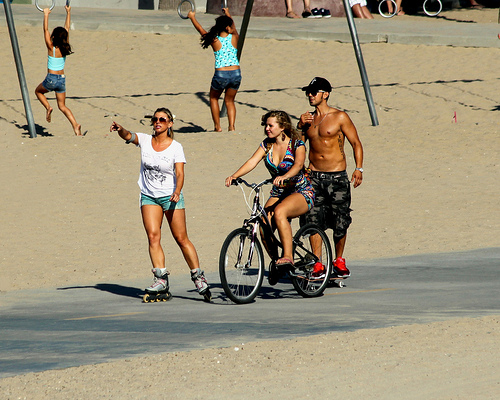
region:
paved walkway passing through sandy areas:
[2, 7, 497, 399]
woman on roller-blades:
[103, 105, 215, 302]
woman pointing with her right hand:
[106, 102, 185, 169]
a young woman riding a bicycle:
[216, 104, 333, 300]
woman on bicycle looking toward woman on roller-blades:
[106, 104, 334, 300]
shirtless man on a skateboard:
[296, 75, 368, 290]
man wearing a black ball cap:
[299, 74, 333, 111]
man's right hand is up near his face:
[290, 73, 371, 187]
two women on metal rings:
[3, 0, 381, 138]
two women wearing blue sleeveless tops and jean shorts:
[33, 1, 249, 131]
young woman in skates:
[109, 107, 216, 304]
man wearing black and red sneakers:
[294, 76, 364, 294]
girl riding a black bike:
[218, 109, 331, 303]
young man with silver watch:
[295, 74, 366, 289]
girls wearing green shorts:
[109, 105, 218, 304]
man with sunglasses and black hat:
[295, 74, 366, 289]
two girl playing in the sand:
[35, 7, 245, 136]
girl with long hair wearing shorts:
[187, 7, 243, 133]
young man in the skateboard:
[293, 76, 365, 288]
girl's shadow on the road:
[56, 279, 206, 319]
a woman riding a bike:
[207, 105, 309, 313]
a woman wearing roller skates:
[129, 104, 194, 325]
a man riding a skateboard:
[307, 57, 344, 305]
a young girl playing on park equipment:
[28, 1, 81, 134]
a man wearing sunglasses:
[289, 70, 333, 125]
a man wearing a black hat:
[302, 78, 334, 113]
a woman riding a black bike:
[223, 97, 300, 282]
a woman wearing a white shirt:
[115, 90, 200, 240]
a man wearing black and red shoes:
[316, 92, 346, 302]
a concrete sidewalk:
[38, 200, 483, 390]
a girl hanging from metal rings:
[21, 1, 98, 143]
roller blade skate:
[133, 267, 185, 307]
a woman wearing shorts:
[103, 96, 221, 332]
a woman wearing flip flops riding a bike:
[206, 103, 339, 306]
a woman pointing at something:
[102, 102, 219, 310]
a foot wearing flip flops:
[271, 252, 303, 277]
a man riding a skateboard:
[282, 67, 368, 290]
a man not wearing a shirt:
[280, 71, 367, 289]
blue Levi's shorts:
[42, 75, 69, 93]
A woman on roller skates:
[109, 110, 211, 302]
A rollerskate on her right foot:
[140, 266, 173, 302]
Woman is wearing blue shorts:
[137, 193, 183, 210]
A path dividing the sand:
[7, 293, 99, 370]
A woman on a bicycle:
[235, 113, 298, 259]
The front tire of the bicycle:
[221, 231, 260, 301]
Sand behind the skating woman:
[49, 161, 121, 248]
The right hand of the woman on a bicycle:
[225, 176, 234, 188]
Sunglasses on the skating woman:
[151, 114, 165, 122]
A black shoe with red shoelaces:
[333, 256, 350, 276]